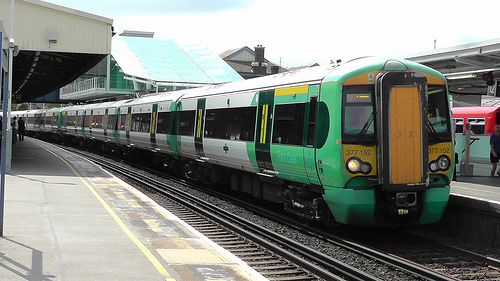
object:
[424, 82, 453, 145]
window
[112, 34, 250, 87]
roof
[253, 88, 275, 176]
door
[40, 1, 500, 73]
sky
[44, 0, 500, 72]
cloud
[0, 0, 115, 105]
awning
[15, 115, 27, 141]
people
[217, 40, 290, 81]
building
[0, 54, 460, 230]
train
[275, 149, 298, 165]
sign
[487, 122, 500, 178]
man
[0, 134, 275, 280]
train platform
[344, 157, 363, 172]
headlight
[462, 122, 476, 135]
woman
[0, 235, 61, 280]
shadow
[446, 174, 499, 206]
road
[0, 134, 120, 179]
pavement shadow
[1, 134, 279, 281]
pavement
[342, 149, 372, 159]
377 152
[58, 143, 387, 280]
train track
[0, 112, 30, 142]
waiting bay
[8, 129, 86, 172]
waiting bay